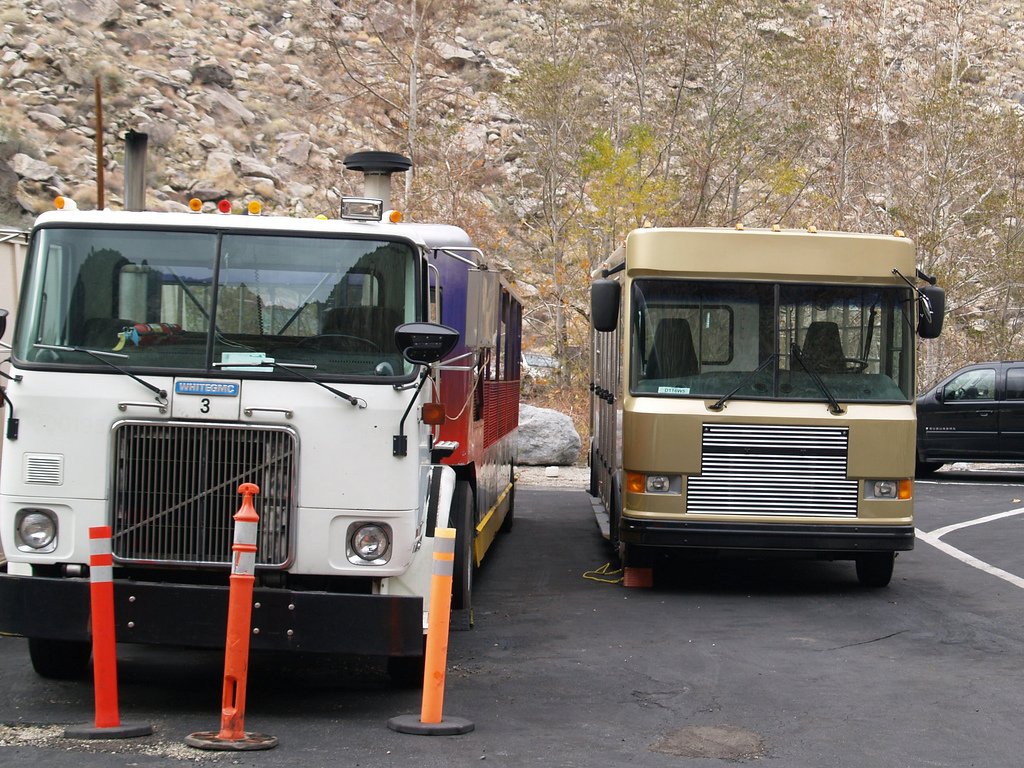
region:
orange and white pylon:
[201, 481, 269, 747]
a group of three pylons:
[33, 475, 477, 766]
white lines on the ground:
[912, 466, 1023, 585]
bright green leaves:
[568, 127, 689, 238]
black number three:
[192, 393, 221, 419]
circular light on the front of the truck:
[340, 515, 391, 573]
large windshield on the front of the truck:
[8, 210, 427, 378]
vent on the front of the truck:
[677, 395, 874, 526]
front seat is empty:
[646, 307, 704, 385]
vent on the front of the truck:
[103, 409, 299, 569]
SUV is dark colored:
[917, 351, 1023, 492]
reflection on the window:
[67, 235, 159, 352]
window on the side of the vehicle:
[940, 360, 999, 399]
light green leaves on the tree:
[579, 130, 696, 239]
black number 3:
[191, 393, 224, 423]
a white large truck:
[35, 142, 555, 716]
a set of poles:
[33, 433, 509, 759]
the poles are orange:
[65, 437, 515, 757]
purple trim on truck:
[418, 258, 555, 377]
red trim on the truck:
[408, 366, 539, 488]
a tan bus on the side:
[574, 217, 958, 601]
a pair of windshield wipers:
[687, 325, 878, 440]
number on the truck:
[153, 361, 243, 426]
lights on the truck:
[1, 497, 416, 596]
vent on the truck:
[89, 104, 198, 241]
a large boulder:
[515, 407, 579, 462]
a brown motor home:
[591, 243, 921, 572]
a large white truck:
[27, 213, 530, 640]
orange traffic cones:
[78, 492, 458, 740]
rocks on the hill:
[33, 43, 837, 168]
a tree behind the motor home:
[510, 49, 795, 242]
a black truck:
[918, 362, 1018, 468]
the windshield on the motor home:
[630, 280, 909, 397]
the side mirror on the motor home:
[586, 276, 618, 321]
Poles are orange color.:
[59, 481, 465, 767]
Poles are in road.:
[62, 497, 481, 744]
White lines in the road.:
[903, 451, 1022, 591]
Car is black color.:
[910, 343, 1021, 521]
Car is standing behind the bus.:
[904, 333, 1022, 474]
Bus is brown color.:
[558, 211, 925, 576]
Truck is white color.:
[10, 194, 491, 656]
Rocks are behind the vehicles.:
[63, 30, 939, 230]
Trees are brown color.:
[351, 34, 982, 216]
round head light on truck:
[340, 518, 391, 563]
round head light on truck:
[13, 509, 75, 560]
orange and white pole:
[215, 470, 274, 739]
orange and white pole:
[70, 518, 132, 728]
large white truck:
[5, 199, 515, 646]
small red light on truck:
[211, 193, 232, 210]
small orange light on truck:
[185, 190, 204, 213]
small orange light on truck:
[49, 192, 70, 211]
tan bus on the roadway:
[578, 212, 955, 615]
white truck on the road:
[2, 120, 533, 712]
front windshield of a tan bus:
[629, 274, 911, 415]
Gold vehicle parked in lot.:
[577, 222, 932, 611]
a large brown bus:
[581, 256, 915, 577]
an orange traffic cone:
[81, 524, 140, 733]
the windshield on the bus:
[43, 233, 404, 363]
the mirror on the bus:
[397, 313, 459, 361]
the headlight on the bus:
[360, 528, 389, 564]